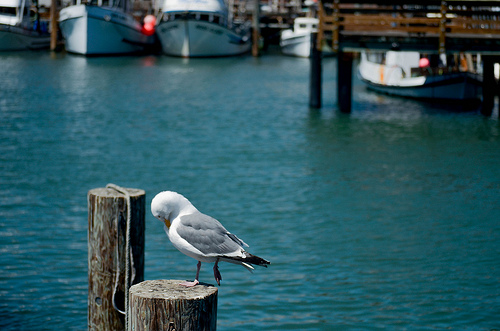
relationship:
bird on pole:
[148, 188, 272, 291] [124, 278, 222, 331]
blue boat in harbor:
[54, 0, 153, 55] [0, 1, 310, 91]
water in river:
[0, 53, 500, 331] [151, 87, 276, 158]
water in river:
[0, 53, 500, 331] [3, 84, 492, 320]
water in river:
[1, 47, 498, 327] [2, 47, 497, 326]